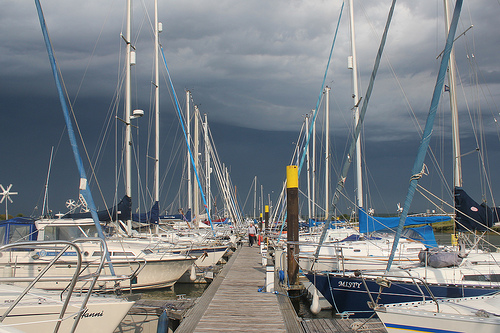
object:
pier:
[172, 247, 304, 333]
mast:
[114, 0, 145, 238]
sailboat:
[364, 292, 498, 333]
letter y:
[357, 282, 363, 288]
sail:
[382, 0, 500, 273]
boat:
[285, 238, 428, 310]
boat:
[303, 252, 500, 318]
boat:
[372, 294, 500, 333]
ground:
[231, 257, 265, 333]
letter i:
[344, 282, 349, 288]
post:
[260, 243, 265, 254]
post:
[265, 264, 275, 292]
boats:
[106, 238, 232, 284]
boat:
[0, 237, 147, 333]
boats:
[0, 242, 198, 293]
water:
[433, 231, 453, 247]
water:
[479, 234, 500, 252]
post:
[286, 165, 300, 311]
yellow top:
[285, 165, 299, 189]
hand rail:
[0, 238, 108, 333]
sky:
[2, 1, 497, 154]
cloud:
[0, 0, 500, 133]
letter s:
[347, 282, 352, 288]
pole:
[346, 0, 364, 208]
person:
[248, 223, 257, 247]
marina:
[0, 219, 500, 333]